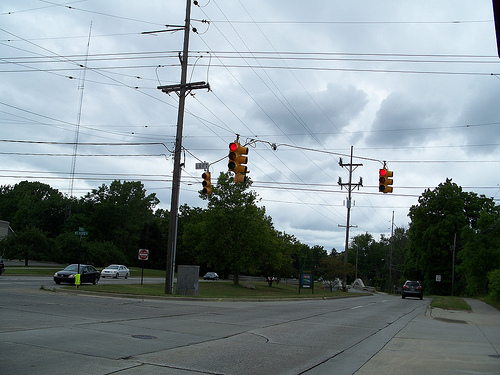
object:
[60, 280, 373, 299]
grass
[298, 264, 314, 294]
sign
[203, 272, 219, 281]
cars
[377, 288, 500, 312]
grass area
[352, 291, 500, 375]
sidewalk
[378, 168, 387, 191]
signal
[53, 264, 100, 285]
car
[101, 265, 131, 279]
car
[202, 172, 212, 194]
street lights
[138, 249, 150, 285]
sign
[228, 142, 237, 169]
signal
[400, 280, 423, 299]
car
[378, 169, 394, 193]
light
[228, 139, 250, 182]
light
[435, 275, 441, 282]
traffic sign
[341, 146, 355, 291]
telephone pole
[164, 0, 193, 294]
telephone pole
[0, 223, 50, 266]
round tree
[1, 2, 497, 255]
clouds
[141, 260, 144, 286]
post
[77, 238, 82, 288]
post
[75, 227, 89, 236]
street sign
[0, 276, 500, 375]
intersection